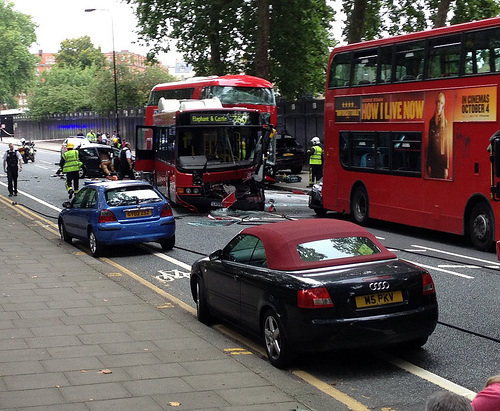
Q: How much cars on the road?
A: Two.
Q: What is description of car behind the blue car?
A: Red and black.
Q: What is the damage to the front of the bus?
A: It is smashed.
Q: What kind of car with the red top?
A: Convertible.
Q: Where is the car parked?
A: At the curb.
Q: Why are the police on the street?
A: To investigate the accident.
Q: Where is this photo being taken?
A: A street in the UK.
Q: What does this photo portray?
A: An automobile accident.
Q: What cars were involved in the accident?
A: A bus and a black car.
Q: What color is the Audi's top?
A: Red.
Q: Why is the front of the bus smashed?
A: It was in an accident.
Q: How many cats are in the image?
A: 0.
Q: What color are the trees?
A: Green.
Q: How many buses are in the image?
A: 3.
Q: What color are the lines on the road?
A: White.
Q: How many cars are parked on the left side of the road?
A: 2.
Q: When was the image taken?
A: Daytime.